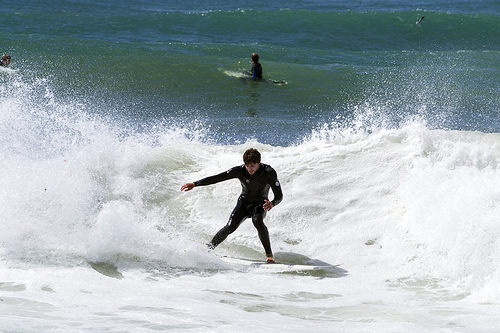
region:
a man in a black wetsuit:
[184, 142, 313, 282]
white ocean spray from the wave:
[4, 78, 156, 259]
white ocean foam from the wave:
[418, 145, 478, 257]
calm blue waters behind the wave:
[286, 18, 378, 54]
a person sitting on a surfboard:
[202, 40, 284, 99]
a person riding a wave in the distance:
[400, 6, 448, 36]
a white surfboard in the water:
[177, 243, 343, 282]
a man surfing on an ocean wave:
[91, 142, 341, 296]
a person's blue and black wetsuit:
[241, 59, 266, 84]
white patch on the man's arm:
[273, 178, 281, 192]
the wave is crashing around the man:
[3, 60, 495, 332]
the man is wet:
[170, 135, 290, 266]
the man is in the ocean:
[173, 138, 286, 259]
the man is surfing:
[175, 140, 288, 266]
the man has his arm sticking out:
[180, 163, 245, 198]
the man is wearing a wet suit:
[170, 137, 298, 260]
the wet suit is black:
[163, 145, 298, 272]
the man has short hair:
[241, 142, 263, 181]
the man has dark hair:
[236, 142, 264, 167]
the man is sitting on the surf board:
[207, 43, 292, 91]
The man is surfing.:
[171, 133, 294, 275]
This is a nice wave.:
[34, 125, 203, 278]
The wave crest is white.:
[31, 120, 203, 272]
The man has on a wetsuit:
[187, 143, 322, 270]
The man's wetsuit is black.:
[198, 138, 325, 271]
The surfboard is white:
[228, 247, 343, 297]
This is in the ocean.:
[109, 10, 449, 247]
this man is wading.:
[208, 39, 308, 109]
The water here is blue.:
[50, 11, 217, 94]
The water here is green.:
[151, 75, 306, 160]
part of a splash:
[318, 103, 354, 178]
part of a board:
[258, 256, 275, 272]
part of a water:
[382, 228, 418, 279]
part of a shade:
[325, 258, 346, 282]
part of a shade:
[288, 243, 315, 270]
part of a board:
[277, 252, 299, 280]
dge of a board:
[279, 242, 301, 282]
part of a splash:
[381, 218, 415, 266]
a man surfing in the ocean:
[187, 145, 285, 261]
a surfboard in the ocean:
[170, 255, 335, 275]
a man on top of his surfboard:
[181, 148, 336, 273]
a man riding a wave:
[180, 147, 343, 277]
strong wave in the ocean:
[348, 124, 497, 286]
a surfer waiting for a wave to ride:
[219, 52, 290, 90]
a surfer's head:
[0, 49, 11, 66]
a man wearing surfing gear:
[187, 146, 287, 261]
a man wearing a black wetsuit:
[190, 153, 278, 256]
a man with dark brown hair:
[242, 147, 262, 175]